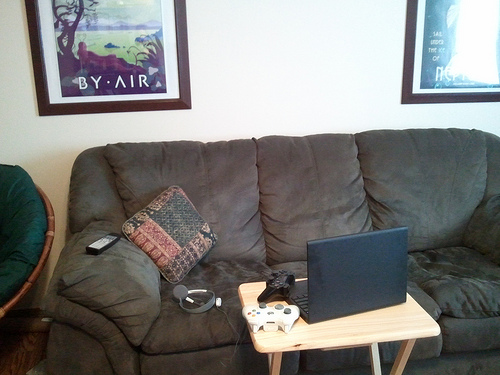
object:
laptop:
[282, 224, 409, 325]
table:
[236, 275, 443, 375]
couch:
[37, 127, 499, 373]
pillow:
[120, 184, 220, 286]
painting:
[21, 0, 193, 118]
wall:
[205, 11, 317, 73]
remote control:
[84, 231, 123, 256]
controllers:
[240, 302, 300, 334]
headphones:
[172, 285, 224, 315]